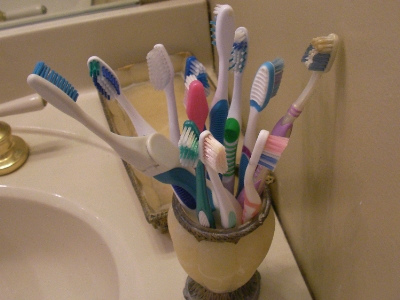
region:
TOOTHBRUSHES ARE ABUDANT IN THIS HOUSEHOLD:
[86, 51, 301, 236]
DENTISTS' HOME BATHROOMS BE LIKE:
[42, 45, 321, 295]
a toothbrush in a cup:
[200, 130, 239, 224]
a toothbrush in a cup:
[174, 119, 210, 229]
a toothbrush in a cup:
[232, 119, 278, 216]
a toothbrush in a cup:
[31, 70, 189, 207]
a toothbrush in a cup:
[88, 56, 159, 144]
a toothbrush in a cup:
[139, 31, 187, 144]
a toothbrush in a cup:
[182, 74, 215, 132]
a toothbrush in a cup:
[208, 4, 231, 114]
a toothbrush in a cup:
[240, 61, 285, 158]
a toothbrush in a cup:
[256, 28, 340, 158]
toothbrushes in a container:
[21, 19, 310, 289]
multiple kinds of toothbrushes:
[38, 17, 350, 257]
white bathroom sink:
[3, 10, 337, 294]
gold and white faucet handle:
[1, 76, 69, 168]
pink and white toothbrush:
[241, 119, 302, 236]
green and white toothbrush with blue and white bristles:
[226, 24, 243, 183]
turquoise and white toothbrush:
[176, 120, 209, 236]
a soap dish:
[84, 52, 262, 235]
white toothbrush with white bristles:
[136, 23, 189, 142]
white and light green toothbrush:
[200, 123, 244, 247]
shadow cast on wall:
[297, 136, 384, 208]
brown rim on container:
[173, 221, 238, 246]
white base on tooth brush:
[138, 119, 183, 169]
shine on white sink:
[12, 178, 115, 221]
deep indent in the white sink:
[24, 236, 77, 280]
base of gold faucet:
[7, 121, 44, 175]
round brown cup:
[152, 175, 309, 292]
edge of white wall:
[29, 8, 134, 54]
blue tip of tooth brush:
[25, 64, 96, 110]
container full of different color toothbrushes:
[29, 21, 392, 251]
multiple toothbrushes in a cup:
[24, 2, 347, 296]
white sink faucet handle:
[0, 84, 53, 184]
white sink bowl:
[1, 182, 129, 298]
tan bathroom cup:
[159, 192, 276, 297]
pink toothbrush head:
[173, 68, 211, 128]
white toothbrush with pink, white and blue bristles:
[238, 118, 289, 219]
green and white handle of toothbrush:
[219, 98, 243, 184]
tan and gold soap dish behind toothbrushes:
[96, 44, 238, 236]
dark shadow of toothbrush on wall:
[312, 41, 350, 231]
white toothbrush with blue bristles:
[23, 60, 88, 125]